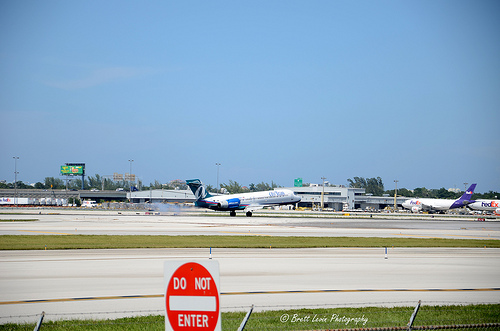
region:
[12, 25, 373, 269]
a white plane flying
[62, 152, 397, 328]
a speeding white plane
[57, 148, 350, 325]
a white plane on a runway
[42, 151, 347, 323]
plane on a runway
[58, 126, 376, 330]
a white plane landing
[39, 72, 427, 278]
white and blue plane landing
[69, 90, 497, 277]
two white and blue planes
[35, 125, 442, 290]
a plane at a airport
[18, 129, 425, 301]
a plane landing at a airport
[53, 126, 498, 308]
fedex plane at a airport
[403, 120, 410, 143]
part of a cloud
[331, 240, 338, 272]
edge of a fence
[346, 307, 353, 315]
part of a fence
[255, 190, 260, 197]
part of a plane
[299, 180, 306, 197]
tip of a plane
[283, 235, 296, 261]
part of a road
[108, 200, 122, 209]
part of a roof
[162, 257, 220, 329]
metal Do Not Enter sign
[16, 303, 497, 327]
patch of green grass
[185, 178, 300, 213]
airplane is about to take off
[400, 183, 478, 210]
white and purple plane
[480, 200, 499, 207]
logo on the white plane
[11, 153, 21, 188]
tall street light post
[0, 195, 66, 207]
line of box trucks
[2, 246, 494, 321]
concrete run way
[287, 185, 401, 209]
airport terminal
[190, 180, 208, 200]
white logo on the plane tale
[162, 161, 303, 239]
this is a plane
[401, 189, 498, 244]
this is a plane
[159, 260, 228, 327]
this is a sign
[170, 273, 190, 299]
a word on the sign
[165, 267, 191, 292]
a word on the sign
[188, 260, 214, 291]
a word on the sign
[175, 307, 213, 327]
a word on the sign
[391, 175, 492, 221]
this is a plane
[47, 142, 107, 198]
this is a sign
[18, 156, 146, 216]
these are trees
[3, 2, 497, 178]
blue of daytime sky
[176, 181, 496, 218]
planes at air terminal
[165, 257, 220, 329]
sign with red circle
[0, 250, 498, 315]
paved surface at airport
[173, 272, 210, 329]
white words on red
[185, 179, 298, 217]
side of white plane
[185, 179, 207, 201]
white design on tail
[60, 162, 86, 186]
green rectangle sign on pole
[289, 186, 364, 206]
terminal with flat roof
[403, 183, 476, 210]
plane with purple tail